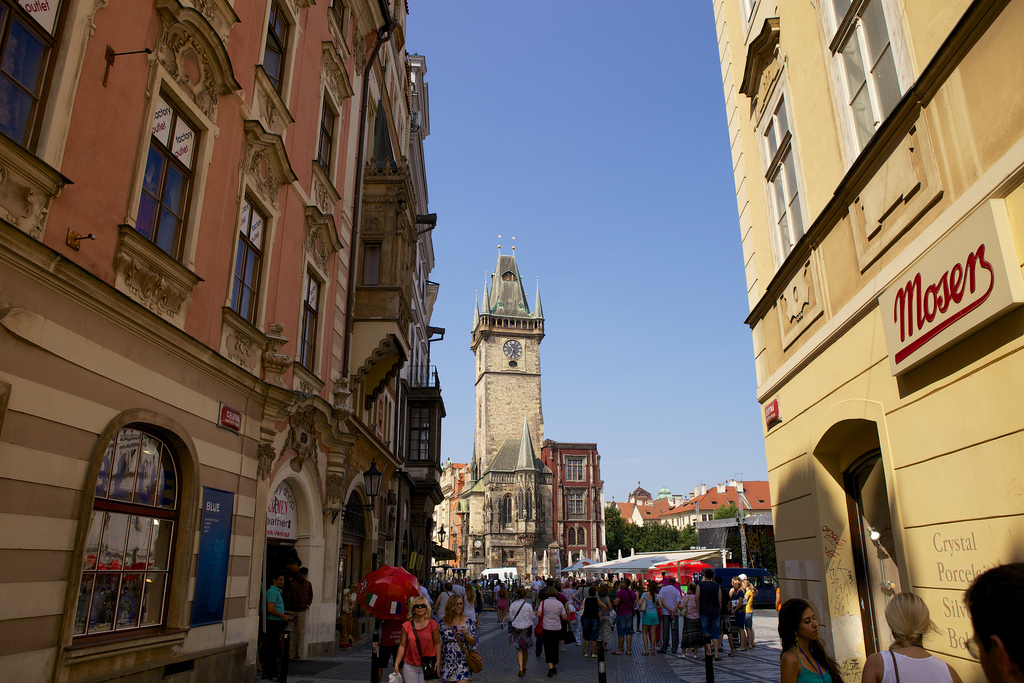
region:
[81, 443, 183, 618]
a window on a building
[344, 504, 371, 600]
a window on a building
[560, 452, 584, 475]
a window on a building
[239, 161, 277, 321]
a window on a building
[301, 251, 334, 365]
a window on a building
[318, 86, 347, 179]
a window on a building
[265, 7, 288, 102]
a window on a building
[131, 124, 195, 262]
a window on a building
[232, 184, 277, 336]
a window on a building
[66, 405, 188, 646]
a window on a building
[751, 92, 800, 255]
a window on a building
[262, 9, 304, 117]
a window on a building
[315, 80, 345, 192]
a window on a building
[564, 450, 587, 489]
a window on a building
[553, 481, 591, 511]
a window on a building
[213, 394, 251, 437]
Small red and white sign on the side of the building.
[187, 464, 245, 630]
Dark blue poster on the side of the building.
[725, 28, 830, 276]
Side of the building with windows on it.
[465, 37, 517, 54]
Clear blue sky with no clouds.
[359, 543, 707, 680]
Bunch of people walking through the buildings.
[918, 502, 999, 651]
Letters on the side of the building.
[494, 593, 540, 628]
Strap across the woman's body.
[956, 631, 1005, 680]
Glasses on the man's face.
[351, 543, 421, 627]
Top of the red umbrella in the man's hands.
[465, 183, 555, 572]
Tallest building by the side of the road.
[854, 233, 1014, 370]
Red and white sign on the side of the building.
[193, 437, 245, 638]
Poster on the side of the building.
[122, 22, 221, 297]
Window on the side of the building.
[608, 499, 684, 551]
Bunch of trees in front of the houses.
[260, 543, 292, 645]
Two people standing under the building.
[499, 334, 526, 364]
the time is 11:36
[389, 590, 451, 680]
this woman is wearing a pink blouse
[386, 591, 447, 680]
this woman has a black handbag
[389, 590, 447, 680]
this woman is wearing dark sunglasses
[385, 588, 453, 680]
this woman is wearing white pants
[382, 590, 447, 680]
this woman is carrying a white bag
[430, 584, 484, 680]
this woman is wearing a printed dress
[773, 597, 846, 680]
Long brown haired woman in green strappy top.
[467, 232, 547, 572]
Tall clock tower with many points on the top.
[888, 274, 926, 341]
Large cursive red M in Moser.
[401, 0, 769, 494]
A blue cloudless sky.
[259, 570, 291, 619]
Black haired man in a doorway with a green shirt on.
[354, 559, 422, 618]
Mostly red opened umbrella.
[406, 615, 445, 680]
Black bag going across a woman in pink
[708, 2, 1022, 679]
Tall yellow building with a Moser sign on the side.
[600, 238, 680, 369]
the sky is clear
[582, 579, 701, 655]
people walking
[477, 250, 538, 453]
a tall building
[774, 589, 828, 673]
a women standing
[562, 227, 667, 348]
the sky is clear and blue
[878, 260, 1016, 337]
a sign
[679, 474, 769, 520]
a building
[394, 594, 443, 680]
a lady walking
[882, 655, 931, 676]
a white shirt